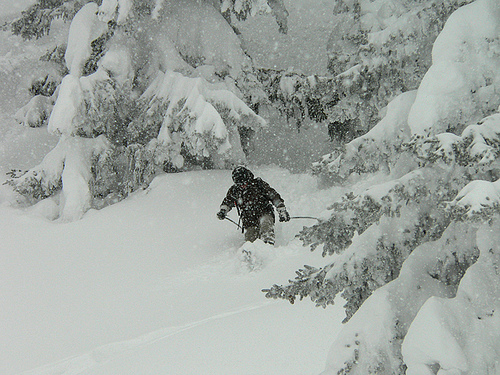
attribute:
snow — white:
[37, 200, 219, 360]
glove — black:
[276, 211, 291, 222]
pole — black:
[277, 203, 327, 230]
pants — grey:
[243, 213, 274, 242]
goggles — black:
[230, 168, 252, 185]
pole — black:
[288, 213, 322, 222]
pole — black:
[225, 213, 249, 233]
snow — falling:
[5, 2, 497, 259]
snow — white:
[2, 115, 492, 372]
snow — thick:
[58, 257, 190, 324]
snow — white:
[99, 276, 236, 366]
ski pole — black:
[222, 214, 243, 236]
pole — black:
[288, 212, 335, 227]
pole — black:
[278, 214, 325, 229]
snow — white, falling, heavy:
[0, 0, 499, 372]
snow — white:
[239, 298, 274, 340]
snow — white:
[10, 190, 275, 374]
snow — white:
[55, 250, 162, 326]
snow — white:
[164, 222, 236, 259]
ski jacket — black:
[221, 164, 286, 224]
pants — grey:
[243, 200, 381, 305]